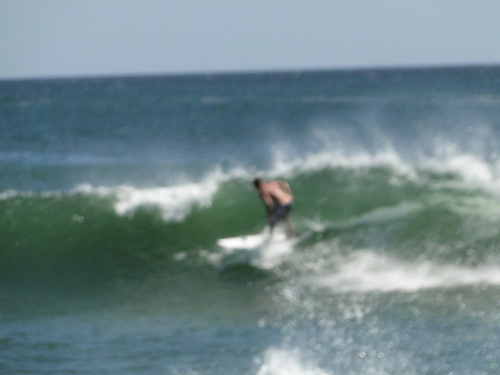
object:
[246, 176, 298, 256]
surfer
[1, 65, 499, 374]
water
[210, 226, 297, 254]
board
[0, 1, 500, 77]
sky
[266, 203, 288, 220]
shorts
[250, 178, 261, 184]
hair